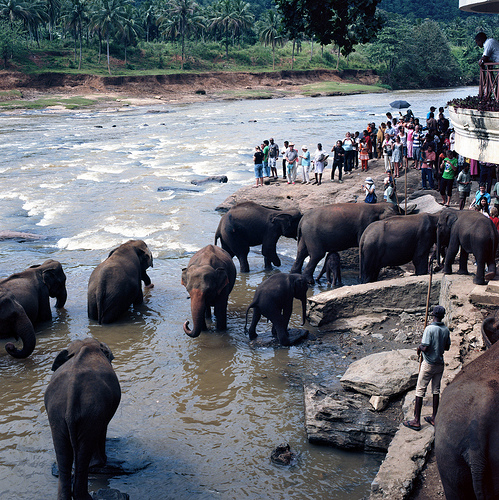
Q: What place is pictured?
A: It is a river.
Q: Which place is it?
A: It is a river.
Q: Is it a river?
A: Yes, it is a river.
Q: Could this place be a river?
A: Yes, it is a river.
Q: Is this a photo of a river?
A: Yes, it is showing a river.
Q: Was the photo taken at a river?
A: Yes, it was taken in a river.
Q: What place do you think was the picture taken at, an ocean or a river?
A: It was taken at a river.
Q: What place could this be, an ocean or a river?
A: It is a river.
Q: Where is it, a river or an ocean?
A: It is a river.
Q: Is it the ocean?
A: No, it is the river.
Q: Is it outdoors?
A: Yes, it is outdoors.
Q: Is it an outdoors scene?
A: Yes, it is outdoors.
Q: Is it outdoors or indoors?
A: It is outdoors.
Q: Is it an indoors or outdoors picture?
A: It is outdoors.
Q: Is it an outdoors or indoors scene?
A: It is outdoors.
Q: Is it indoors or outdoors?
A: It is outdoors.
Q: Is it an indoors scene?
A: No, it is outdoors.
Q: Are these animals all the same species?
A: Yes, all the animals are elephants.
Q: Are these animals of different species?
A: No, all the animals are elephants.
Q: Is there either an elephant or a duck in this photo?
A: Yes, there is an elephant.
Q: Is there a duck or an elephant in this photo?
A: Yes, there is an elephant.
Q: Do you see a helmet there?
A: No, there are no helmets.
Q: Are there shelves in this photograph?
A: No, there are no shelves.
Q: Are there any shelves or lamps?
A: No, there are no shelves or lamps.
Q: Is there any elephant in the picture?
A: Yes, there is an elephant.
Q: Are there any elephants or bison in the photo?
A: Yes, there is an elephant.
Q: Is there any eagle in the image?
A: No, there are no eagles.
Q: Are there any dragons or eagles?
A: No, there are no eagles or dragons.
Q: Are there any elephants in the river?
A: Yes, there is an elephant in the river.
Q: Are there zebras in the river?
A: No, there is an elephant in the river.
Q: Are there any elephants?
A: Yes, there is an elephant.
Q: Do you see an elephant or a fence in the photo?
A: Yes, there is an elephant.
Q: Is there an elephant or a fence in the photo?
A: Yes, there is an elephant.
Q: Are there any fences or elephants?
A: Yes, there is an elephant.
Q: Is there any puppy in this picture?
A: No, there are no puppys.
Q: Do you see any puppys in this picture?
A: No, there are no puppys.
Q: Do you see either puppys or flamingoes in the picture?
A: No, there are no puppys or flamingoes.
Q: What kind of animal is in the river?
A: The animal is an elephant.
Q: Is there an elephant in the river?
A: Yes, there is an elephant in the river.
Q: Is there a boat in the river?
A: No, there is an elephant in the river.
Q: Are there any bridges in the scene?
A: No, there are no bridges.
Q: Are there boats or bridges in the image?
A: No, there are no bridges or boats.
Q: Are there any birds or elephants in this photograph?
A: Yes, there is an elephant.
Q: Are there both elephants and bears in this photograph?
A: No, there is an elephant but no bears.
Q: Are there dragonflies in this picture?
A: No, there are no dragonflies.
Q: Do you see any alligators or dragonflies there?
A: No, there are no dragonflies or alligators.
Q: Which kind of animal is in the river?
A: The animal is an elephant.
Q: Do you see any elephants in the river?
A: Yes, there is an elephant in the river.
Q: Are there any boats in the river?
A: No, there is an elephant in the river.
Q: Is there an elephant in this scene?
A: Yes, there is an elephant.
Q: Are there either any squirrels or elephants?
A: Yes, there is an elephant.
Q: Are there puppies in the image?
A: No, there are no puppies.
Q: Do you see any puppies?
A: No, there are no puppies.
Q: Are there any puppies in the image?
A: No, there are no puppies.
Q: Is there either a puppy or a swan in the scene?
A: No, there are no puppies or swans.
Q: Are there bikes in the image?
A: No, there are no bikes.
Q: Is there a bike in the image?
A: No, there are no bikes.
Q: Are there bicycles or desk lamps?
A: No, there are no bicycles or desk lamps.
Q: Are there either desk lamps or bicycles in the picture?
A: No, there are no bicycles or desk lamps.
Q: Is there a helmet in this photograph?
A: No, there are no helmets.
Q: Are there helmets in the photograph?
A: No, there are no helmets.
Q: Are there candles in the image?
A: No, there are no candles.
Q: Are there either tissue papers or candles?
A: No, there are no candles or tissue papers.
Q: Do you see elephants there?
A: Yes, there is an elephant.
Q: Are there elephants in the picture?
A: Yes, there is an elephant.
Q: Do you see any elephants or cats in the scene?
A: Yes, there is an elephant.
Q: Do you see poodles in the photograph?
A: No, there are no poodles.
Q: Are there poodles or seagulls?
A: No, there are no poodles or seagulls.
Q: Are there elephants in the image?
A: Yes, there is an elephant.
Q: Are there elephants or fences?
A: Yes, there is an elephant.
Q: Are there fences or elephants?
A: Yes, there is an elephant.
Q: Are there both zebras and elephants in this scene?
A: No, there is an elephant but no zebras.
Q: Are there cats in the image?
A: No, there are no cats.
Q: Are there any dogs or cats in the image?
A: No, there are no cats or dogs.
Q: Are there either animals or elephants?
A: Yes, there is an elephant.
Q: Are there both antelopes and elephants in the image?
A: No, there is an elephant but no antelopes.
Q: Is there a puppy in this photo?
A: No, there are no puppies.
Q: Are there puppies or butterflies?
A: No, there are no puppies or butterflies.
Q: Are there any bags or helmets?
A: No, there are no helmets or bags.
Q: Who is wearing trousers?
A: The man is wearing trousers.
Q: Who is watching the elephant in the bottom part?
A: The man is watching the elephant.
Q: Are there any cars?
A: No, there are no cars.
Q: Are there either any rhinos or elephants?
A: Yes, there is an elephant.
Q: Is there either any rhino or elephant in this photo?
A: Yes, there is an elephant.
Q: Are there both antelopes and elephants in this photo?
A: No, there is an elephant but no antelopes.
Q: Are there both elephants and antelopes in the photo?
A: No, there is an elephant but no antelopes.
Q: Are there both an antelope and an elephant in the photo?
A: No, there is an elephant but no antelopes.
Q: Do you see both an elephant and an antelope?
A: No, there is an elephant but no antelopes.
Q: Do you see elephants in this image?
A: Yes, there is an elephant.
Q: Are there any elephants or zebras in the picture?
A: Yes, there is an elephant.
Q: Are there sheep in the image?
A: No, there are no sheep.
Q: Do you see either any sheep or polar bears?
A: No, there are no sheep or polar bears.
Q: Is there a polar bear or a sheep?
A: No, there are no sheep or polar bears.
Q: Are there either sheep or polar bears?
A: No, there are no sheep or polar bears.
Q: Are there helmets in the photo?
A: No, there are no helmets.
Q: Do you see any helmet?
A: No, there are no helmets.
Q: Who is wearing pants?
A: The man is wearing pants.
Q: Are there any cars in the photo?
A: No, there are no cars.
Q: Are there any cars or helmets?
A: No, there are no cars or helmets.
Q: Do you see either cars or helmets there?
A: No, there are no cars or helmets.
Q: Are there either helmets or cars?
A: No, there are no cars or helmets.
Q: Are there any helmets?
A: No, there are no helmets.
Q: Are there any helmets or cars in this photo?
A: No, there are no helmets or cars.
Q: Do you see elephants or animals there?
A: Yes, there is an elephant.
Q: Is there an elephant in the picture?
A: Yes, there is an elephant.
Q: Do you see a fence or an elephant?
A: Yes, there is an elephant.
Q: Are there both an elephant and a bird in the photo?
A: No, there is an elephant but no birds.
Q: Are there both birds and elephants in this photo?
A: No, there is an elephant but no birds.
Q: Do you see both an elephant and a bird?
A: No, there is an elephant but no birds.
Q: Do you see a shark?
A: No, there are no sharks.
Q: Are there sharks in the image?
A: No, there are no sharks.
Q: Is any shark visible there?
A: No, there are no sharks.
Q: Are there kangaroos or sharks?
A: No, there are no sharks or kangaroos.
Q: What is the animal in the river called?
A: The animal is an elephant.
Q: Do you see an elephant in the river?
A: Yes, there is an elephant in the river.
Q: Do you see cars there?
A: No, there are no cars.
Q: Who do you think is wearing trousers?
A: The man is wearing trousers.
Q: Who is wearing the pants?
A: The man is wearing trousers.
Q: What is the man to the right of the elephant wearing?
A: The man is wearing pants.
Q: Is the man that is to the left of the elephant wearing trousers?
A: Yes, the man is wearing trousers.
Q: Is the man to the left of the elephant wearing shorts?
A: No, the man is wearing trousers.